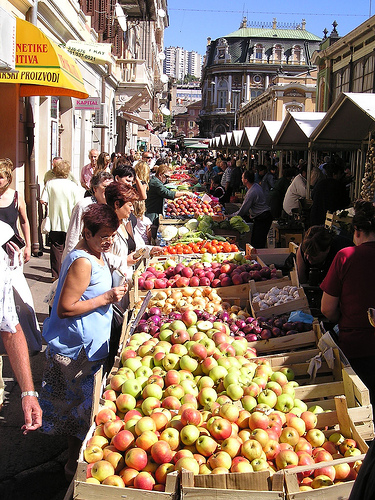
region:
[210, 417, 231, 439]
a red and yellow apple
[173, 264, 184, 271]
a red apple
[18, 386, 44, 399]
a watch on a man's wrist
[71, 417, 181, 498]
a wooden box holding apples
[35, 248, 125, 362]
a blue shirt on a woman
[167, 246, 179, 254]
a red tomato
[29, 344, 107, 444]
a tan and white patterned skirt on a woman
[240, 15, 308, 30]
a decorative railing on top of a building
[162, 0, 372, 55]
a clear blue sky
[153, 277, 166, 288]
red colored fresh apple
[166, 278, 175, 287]
red colored fresh apple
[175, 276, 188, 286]
red colored fresh apple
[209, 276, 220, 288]
red colored fresh apple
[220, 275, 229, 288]
red colored fresh apple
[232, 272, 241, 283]
red colored fresh apple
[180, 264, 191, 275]
red colored fresh apple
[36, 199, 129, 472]
Woman wearing a blue shirt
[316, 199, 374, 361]
Woman wearing a red shirt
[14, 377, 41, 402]
Watch on the man's wrist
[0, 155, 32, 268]
Woman wearing a black tank top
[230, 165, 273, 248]
Man wearing black pants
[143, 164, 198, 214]
Lady picking through fruit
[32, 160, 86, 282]
Lady wearing brown pants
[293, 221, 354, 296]
Woman bending over near fruit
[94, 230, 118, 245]
Glasses on the woman's face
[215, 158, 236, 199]
Man wearing a striped shirt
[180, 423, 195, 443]
green colored apple for sale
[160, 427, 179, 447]
green colored apple for sale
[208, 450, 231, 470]
green colored apple for sale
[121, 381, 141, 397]
green colored apple for sale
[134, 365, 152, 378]
green colored apple for sale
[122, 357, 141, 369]
green colored apple for sale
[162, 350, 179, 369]
green colored apple for sale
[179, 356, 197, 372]
green colored apple for sale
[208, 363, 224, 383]
green colored apple for sale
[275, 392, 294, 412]
green colored apple for sale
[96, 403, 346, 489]
green and red apples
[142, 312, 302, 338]
red apples in box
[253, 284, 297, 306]
white onions in box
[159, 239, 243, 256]
red tomatoes in box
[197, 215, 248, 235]
lettuce heads in box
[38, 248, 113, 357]
blue cotton tank top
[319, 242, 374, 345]
red cotton tee shirt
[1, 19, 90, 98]
yellow awning on building